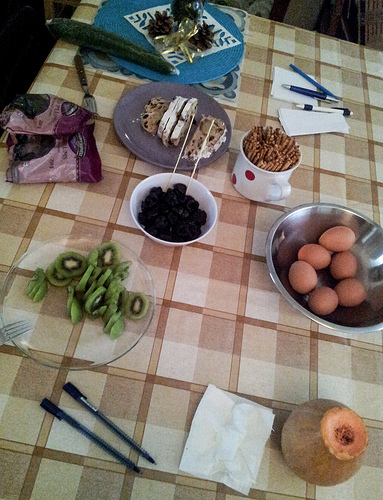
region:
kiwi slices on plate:
[22, 228, 133, 345]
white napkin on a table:
[161, 379, 284, 493]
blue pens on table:
[25, 379, 177, 494]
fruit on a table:
[274, 376, 360, 493]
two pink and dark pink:
[12, 81, 90, 219]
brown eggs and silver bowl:
[269, 234, 377, 330]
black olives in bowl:
[134, 175, 218, 237]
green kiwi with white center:
[114, 286, 155, 334]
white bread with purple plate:
[124, 81, 239, 165]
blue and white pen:
[269, 99, 359, 146]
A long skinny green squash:
[46, 17, 180, 76]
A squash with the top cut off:
[280, 397, 368, 486]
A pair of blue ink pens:
[40, 381, 158, 475]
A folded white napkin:
[179, 383, 274, 495]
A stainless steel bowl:
[264, 202, 381, 333]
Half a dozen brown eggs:
[288, 224, 367, 315]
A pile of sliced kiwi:
[25, 241, 148, 338]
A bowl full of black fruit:
[129, 173, 218, 246]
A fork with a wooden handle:
[74, 53, 97, 115]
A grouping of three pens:
[282, 63, 352, 115]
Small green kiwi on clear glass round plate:
[56, 249, 86, 273]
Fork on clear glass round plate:
[0, 315, 33, 359]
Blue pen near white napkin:
[60, 379, 160, 467]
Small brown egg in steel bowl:
[290, 260, 317, 293]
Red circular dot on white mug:
[244, 167, 256, 182]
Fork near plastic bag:
[71, 52, 98, 117]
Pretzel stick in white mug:
[245, 145, 254, 161]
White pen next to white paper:
[295, 100, 355, 119]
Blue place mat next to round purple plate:
[95, 0, 246, 83]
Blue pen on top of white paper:
[280, 82, 347, 103]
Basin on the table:
[266, 202, 382, 332]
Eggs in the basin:
[288, 223, 367, 313]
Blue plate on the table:
[93, 0, 244, 84]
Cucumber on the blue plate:
[44, 16, 182, 75]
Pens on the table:
[38, 63, 353, 474]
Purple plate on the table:
[113, 80, 231, 169]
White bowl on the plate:
[129, 172, 218, 246]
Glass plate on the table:
[0, 232, 155, 370]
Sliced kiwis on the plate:
[26, 242, 149, 337]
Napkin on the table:
[178, 384, 274, 496]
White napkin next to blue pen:
[177, 380, 275, 494]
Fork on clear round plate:
[0, 314, 35, 351]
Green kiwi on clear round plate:
[56, 252, 83, 276]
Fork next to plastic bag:
[70, 51, 98, 117]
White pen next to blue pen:
[291, 95, 354, 113]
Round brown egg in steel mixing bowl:
[318, 223, 355, 249]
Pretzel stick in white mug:
[257, 157, 264, 166]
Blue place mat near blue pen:
[94, 0, 245, 85]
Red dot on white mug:
[244, 168, 256, 182]